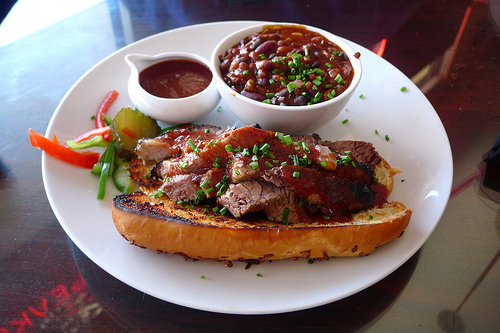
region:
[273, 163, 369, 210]
This is a piece of meet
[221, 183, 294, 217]
This is a piece of meet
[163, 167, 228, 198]
This is a piece of meet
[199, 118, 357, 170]
This is a piece of meet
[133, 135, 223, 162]
This is a piece of meet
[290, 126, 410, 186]
This is a piece of meet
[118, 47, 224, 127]
This is a sauce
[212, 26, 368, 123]
This is a sauce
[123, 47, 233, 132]
This is a saucer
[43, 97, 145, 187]
This is a vegetables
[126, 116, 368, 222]
sauce on the meat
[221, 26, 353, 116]
beans in a bowl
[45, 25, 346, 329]
food on the plate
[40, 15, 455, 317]
The plate is round.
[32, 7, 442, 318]
The plate is white.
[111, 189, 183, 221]
The bread is burnt.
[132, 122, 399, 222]
The meat is on the bread.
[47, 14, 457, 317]
Food is on the plate.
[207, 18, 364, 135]
The bowl is round.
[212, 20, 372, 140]
The bowl is white.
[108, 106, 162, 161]
A pickle is on the plate.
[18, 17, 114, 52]
The table is made of glass.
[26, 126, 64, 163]
The food is orange.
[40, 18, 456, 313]
round white ceramic plate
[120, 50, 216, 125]
small white gravy bowl on plate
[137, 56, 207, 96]
red gravy in gravy bowl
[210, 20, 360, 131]
small white bowl on plate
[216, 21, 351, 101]
red beans in sauce in bowl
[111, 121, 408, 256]
toasted sandwhich with meat on plate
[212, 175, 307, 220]
cooked piece of meat on sandwhich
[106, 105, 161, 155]
sliced green pickle on plate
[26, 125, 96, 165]
sliced red pepper on plate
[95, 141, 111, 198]
sliced green pepper on plate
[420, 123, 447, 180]
A white plate in the picture.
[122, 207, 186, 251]
A sausage in the photo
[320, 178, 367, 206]
Meat in the photo.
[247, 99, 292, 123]
A bowl in the photo.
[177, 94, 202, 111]
A cup in the picture.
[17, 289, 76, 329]
Writings in the photo.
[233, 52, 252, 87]
Brown cereals in the bowl.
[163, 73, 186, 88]
Soup in the picture.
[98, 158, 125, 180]
Vegetables in the photo.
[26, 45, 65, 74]
Glass table in the table.